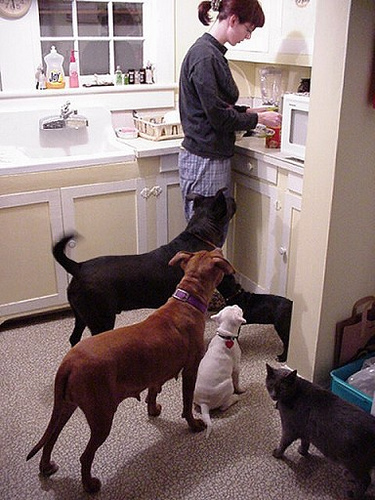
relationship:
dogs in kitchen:
[96, 215, 306, 415] [10, 15, 338, 226]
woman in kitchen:
[171, 4, 268, 168] [10, 15, 338, 226]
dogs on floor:
[96, 215, 306, 415] [144, 414, 271, 495]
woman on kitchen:
[171, 4, 268, 168] [10, 15, 338, 226]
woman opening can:
[171, 4, 268, 168] [262, 125, 288, 159]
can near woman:
[262, 125, 288, 159] [171, 4, 268, 168]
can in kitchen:
[262, 125, 288, 159] [10, 15, 338, 226]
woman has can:
[171, 4, 268, 168] [262, 125, 288, 159]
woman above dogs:
[171, 4, 268, 168] [96, 215, 306, 415]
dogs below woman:
[96, 215, 306, 415] [171, 4, 268, 168]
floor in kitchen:
[144, 414, 271, 495] [10, 15, 338, 226]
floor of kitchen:
[144, 414, 271, 495] [10, 15, 338, 226]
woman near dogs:
[171, 4, 268, 168] [96, 215, 306, 415]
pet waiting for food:
[188, 298, 255, 435] [263, 125, 281, 145]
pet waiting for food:
[47, 182, 241, 259] [263, 125, 281, 145]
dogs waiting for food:
[204, 267, 293, 361] [263, 125, 281, 145]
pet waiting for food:
[25, 249, 215, 489] [263, 125, 281, 145]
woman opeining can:
[176, 2, 283, 194] [264, 125, 280, 147]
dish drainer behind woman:
[131, 113, 180, 140] [176, 2, 283, 194]